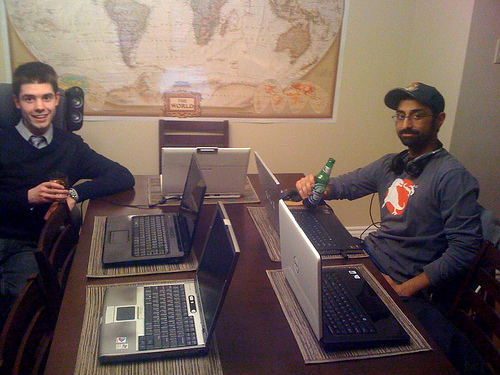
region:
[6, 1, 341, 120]
a map of the world is on the wall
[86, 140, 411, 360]
laptops are open on the table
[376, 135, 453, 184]
headphones are around the man's neck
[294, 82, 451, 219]
the man is drinking a beer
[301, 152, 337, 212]
the beer is in a green bottle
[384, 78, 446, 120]
a black cap is on the man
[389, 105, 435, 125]
the man is wearing eye glasses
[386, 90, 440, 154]
the man has a full beard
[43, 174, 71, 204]
the man has a beverage in a glass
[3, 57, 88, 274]
the person is sitting in a high back chair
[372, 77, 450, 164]
man wearing a hat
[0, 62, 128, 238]
man having a drink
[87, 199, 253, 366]
silver laptop on the table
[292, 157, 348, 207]
a green bottle beer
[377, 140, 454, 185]
headphones around his neck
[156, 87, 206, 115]
a label for the map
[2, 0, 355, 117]
a poster on the wall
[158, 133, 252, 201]
white laptop computer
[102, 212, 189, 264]
black keyboard on a laptop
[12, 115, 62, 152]
collar of a shirt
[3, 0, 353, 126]
A world map is on the wall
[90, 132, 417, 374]
Five computer laptops on the table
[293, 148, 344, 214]
A man is holding a beer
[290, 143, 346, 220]
The beer bottle is green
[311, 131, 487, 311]
Person is wearing a long gray shirt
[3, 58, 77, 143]
Man has short dark hair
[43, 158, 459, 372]
The table is made out of wood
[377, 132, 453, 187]
Man has headphones around his neck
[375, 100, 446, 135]
Man is wearing eyeglasses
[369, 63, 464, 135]
Man is wearing a black cap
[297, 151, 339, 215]
Green Heineken beer bottle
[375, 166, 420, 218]
White dinosaur screen-printed on shirt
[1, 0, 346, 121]
World map on wall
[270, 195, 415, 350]
Open laptop on placemat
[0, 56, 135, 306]
Young man wearing a tie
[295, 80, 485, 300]
Young man wearing a baseball cap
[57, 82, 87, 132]
Speakers attached to chair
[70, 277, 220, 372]
Striped placemat on table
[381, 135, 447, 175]
Headphones around neck of young man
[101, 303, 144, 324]
Trackpad on laptop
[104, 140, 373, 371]
five laptops on a table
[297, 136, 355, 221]
man holding a beer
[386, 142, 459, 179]
headphones around a man's neck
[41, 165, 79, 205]
man holding a glass of liquor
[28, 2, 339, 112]
map of the world on the wall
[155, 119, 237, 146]
tip of a wooden chair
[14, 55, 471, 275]
two men sitting at a table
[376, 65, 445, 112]
man wearing a black cap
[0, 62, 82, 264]
man sitting on a swiveling chair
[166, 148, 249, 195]
lid of a silver laptop